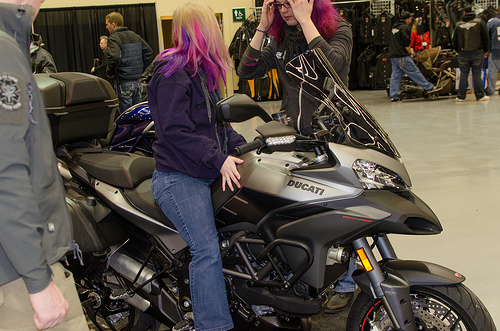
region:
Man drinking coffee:
[93, 16, 120, 66]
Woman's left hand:
[212, 150, 258, 197]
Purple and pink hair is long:
[156, 21, 232, 86]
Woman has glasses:
[273, 4, 298, 8]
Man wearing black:
[379, 7, 442, 94]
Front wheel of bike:
[337, 252, 494, 328]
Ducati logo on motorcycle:
[281, 166, 338, 201]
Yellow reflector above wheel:
[356, 243, 377, 278]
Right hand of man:
[21, 282, 75, 319]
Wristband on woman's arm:
[249, 18, 270, 42]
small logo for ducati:
[272, 170, 332, 206]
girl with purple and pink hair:
[137, 0, 242, 95]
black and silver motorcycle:
[3, 43, 495, 328]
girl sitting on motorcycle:
[111, 0, 272, 329]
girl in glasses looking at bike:
[231, 2, 447, 234]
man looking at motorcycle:
[1, 0, 142, 329]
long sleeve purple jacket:
[131, 41, 253, 195]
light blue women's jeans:
[139, 160, 246, 330]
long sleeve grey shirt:
[233, 15, 370, 137]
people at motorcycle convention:
[366, 1, 499, 112]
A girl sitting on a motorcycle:
[42, 4, 449, 329]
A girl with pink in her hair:
[145, 1, 256, 109]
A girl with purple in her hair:
[150, 4, 246, 113]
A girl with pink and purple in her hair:
[139, 5, 242, 95]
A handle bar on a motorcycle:
[208, 120, 338, 167]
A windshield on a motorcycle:
[267, 40, 431, 199]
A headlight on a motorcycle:
[345, 137, 419, 214]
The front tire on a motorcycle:
[337, 245, 492, 330]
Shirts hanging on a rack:
[355, 4, 400, 88]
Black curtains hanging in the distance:
[24, 2, 169, 122]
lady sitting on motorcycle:
[48, 3, 475, 329]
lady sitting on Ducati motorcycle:
[57, 6, 467, 318]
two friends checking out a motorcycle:
[119, 1, 440, 328]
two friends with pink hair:
[142, 1, 381, 327]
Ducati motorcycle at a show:
[48, 131, 492, 329]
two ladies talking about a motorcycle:
[110, 1, 406, 325]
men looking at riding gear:
[367, 7, 498, 106]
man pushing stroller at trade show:
[379, 2, 459, 119]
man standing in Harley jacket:
[436, 3, 497, 105]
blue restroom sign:
[226, 3, 250, 28]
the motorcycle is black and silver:
[31, 48, 499, 326]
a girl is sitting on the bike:
[137, 6, 243, 329]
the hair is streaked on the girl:
[148, 2, 235, 94]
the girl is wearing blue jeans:
[151, 162, 236, 329]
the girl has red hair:
[260, 3, 340, 43]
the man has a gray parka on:
[4, 13, 79, 292]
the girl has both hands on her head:
[240, 1, 349, 68]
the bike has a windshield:
[276, 44, 433, 241]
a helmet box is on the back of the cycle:
[28, 67, 122, 157]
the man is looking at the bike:
[7, 2, 384, 317]